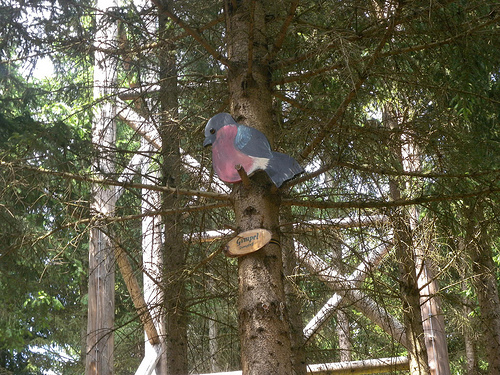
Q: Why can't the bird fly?
A: It is wooden.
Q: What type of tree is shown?
A: Pine.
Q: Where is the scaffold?
A: Behind the pine tree.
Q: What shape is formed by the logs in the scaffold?
A: A cross.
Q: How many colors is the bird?
A: Three.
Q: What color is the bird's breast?
A: Red.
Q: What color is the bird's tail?
A: Black.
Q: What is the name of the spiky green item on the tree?
A: Needle.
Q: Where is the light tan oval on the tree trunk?
A: Beneath the bird.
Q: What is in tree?
A: Red black and white bird.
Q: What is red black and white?
A: Bird in tree.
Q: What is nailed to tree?
A: Wooden bird.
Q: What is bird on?
A: Trunk of large pine tree.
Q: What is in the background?
A: Large wooden framework.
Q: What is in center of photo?
A: Pine tree with two pieces of wood nailed to it.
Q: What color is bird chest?
A: Red.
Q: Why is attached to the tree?
A: Bird.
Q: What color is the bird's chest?
A: Red.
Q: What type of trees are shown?
A: Evergreen.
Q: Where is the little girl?
A: No girl.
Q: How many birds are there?
A: One.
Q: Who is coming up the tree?
A: No one.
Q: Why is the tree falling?
A: No tree falling.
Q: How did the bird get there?
A: A man or woman put it there.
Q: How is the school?
A: No.school.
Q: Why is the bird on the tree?
A: Decoration.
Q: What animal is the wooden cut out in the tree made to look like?
A: Bird.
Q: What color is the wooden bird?
A: Black and red.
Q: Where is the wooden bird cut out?
A: Tree.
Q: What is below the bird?
A: Oval sign.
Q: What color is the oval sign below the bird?
A: Gold.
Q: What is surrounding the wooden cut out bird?
A: Trees.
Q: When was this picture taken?
A: It was taken in the day time.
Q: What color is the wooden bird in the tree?
A: The wooden bird is blue,white, and red.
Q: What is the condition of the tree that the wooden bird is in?
A: The tree looks good and healthy.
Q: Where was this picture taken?
A: The picture was taken in the woods.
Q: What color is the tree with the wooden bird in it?
A: The tree is brown.